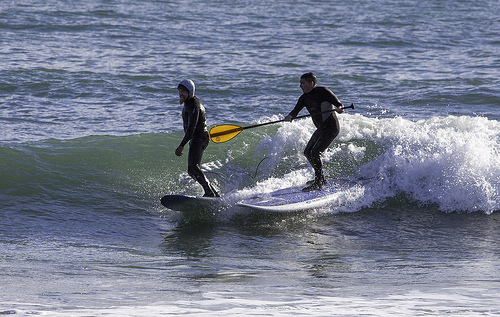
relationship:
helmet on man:
[176, 77, 208, 99] [172, 78, 232, 196]